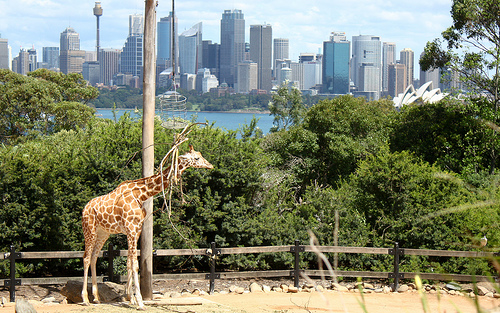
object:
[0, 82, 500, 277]
bushes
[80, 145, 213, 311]
giraffe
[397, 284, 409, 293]
rock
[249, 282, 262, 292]
rock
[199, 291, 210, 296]
rock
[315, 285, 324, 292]
rock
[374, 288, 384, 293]
rock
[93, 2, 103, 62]
tower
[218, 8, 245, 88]
skyscrapers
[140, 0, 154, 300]
pole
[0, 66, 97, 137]
tree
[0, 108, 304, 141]
water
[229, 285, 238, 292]
rocks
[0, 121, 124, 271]
tree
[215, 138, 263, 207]
tree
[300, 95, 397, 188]
tree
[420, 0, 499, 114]
tree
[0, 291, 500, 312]
dirt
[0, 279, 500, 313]
ground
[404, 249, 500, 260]
skateboard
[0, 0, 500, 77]
sky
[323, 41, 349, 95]
building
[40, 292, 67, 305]
rock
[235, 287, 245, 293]
rock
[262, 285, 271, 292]
rock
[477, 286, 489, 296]
rock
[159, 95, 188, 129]
basket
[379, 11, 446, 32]
cloud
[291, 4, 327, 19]
cloud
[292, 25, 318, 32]
cloud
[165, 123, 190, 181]
hay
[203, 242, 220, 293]
reinforcement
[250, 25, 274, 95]
buildings.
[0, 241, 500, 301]
fence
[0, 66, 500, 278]
hillside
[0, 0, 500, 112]
city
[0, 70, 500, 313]
zoo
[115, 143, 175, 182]
food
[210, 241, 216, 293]
post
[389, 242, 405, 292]
support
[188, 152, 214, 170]
face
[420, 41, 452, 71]
leaves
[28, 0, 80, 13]
clouds